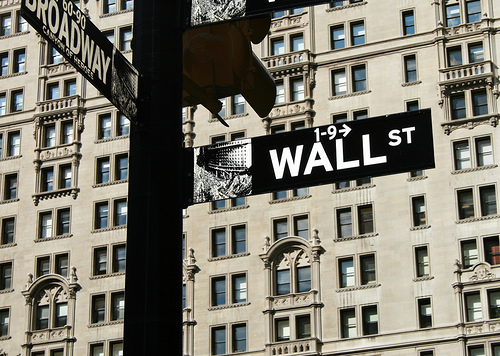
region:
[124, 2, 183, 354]
a black pole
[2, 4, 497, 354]
a large gray apartment building in New York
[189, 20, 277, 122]
a yellow traffic signal on the back of the pole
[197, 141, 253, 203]
black and white photo on Wall St. sign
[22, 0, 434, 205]
two black street signs with white lettering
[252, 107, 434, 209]
the sign for Wall street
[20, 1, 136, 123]
a sign for Broadway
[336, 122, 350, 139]
a small arrow pointing right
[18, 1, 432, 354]
two street signs on a black pole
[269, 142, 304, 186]
white letter on sign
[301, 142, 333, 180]
white letter on sign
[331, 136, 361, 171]
white letter on sign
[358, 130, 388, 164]
white letter on sign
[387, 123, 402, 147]
white letter on sign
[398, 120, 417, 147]
white letter on sign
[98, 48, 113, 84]
white letter on sign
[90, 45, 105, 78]
white letter on sign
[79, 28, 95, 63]
white letter on sign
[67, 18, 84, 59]
white letter on sign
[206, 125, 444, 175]
black and white street sign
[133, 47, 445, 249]
street sign on a post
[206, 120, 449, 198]
black sign with white letters and numbers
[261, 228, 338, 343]
windows on a large building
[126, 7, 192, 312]
large black post holding street signs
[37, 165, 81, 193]
window on side of building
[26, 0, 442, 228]
two street signs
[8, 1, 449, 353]
large light colored building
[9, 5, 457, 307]
large building with multiple windows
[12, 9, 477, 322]
big building behind street sign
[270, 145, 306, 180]
white letter on sign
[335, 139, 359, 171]
white letter on sign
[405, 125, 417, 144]
white letter on sign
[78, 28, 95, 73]
white letter on sign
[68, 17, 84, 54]
white letter on sign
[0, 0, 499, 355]
the large building behind the street signs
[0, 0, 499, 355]
the multiple windows on the building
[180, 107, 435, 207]
the sign that says WALL ST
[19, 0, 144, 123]
the sign that says BROADWAY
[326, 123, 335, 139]
the number 9 on the sign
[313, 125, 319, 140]
the number 1 on the sign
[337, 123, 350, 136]
the white arrow on the sign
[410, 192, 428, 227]
the window on the building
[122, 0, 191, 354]
the pole for the signs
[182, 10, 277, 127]
the traffic light sticking out from the pole